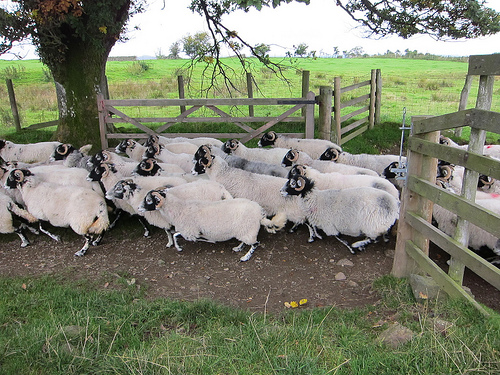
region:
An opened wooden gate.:
[325, 71, 384, 143]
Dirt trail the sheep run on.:
[3, 227, 395, 307]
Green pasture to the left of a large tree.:
[2, 59, 54, 126]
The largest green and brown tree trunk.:
[16, 2, 129, 146]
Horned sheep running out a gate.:
[0, 129, 499, 256]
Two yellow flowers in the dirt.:
[285, 299, 307, 307]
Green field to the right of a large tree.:
[107, 57, 496, 114]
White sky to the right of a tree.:
[115, 3, 499, 54]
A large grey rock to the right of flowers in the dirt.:
[408, 272, 475, 306]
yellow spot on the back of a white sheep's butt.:
[86, 216, 102, 228]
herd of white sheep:
[25, 129, 413, 282]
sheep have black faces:
[273, 172, 318, 219]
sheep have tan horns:
[294, 164, 306, 201]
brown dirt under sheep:
[208, 256, 333, 301]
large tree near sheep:
[28, 3, 123, 156]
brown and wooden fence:
[108, 64, 378, 170]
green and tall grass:
[51, 272, 436, 368]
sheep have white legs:
[163, 227, 267, 267]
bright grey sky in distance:
[248, 6, 325, 38]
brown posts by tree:
[104, 66, 321, 119]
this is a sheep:
[143, 196, 269, 256]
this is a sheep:
[289, 180, 392, 248]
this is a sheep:
[326, 144, 418, 175]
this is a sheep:
[259, 128, 337, 159]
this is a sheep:
[221, 137, 282, 168]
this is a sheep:
[196, 158, 291, 203]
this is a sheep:
[117, 182, 164, 199]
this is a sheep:
[55, 134, 90, 161]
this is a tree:
[47, 7, 117, 109]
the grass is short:
[101, 311, 163, 353]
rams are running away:
[0, 131, 498, 267]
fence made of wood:
[388, 53, 498, 333]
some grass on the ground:
[0, 270, 499, 373]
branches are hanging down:
[176, 0, 298, 116]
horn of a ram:
[293, 175, 304, 190]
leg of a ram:
[240, 243, 256, 260]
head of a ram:
[138, 188, 168, 213]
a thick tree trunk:
[22, 0, 129, 142]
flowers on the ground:
[282, 298, 307, 308]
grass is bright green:
[1, 59, 498, 141]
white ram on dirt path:
[21, 176, 109, 251]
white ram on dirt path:
[20, 163, 102, 195]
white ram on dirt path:
[159, 191, 276, 258]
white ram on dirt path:
[88, 167, 185, 223]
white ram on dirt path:
[290, 183, 387, 248]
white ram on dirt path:
[231, 141, 285, 162]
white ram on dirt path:
[263, 129, 342, 164]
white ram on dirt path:
[330, 149, 408, 175]